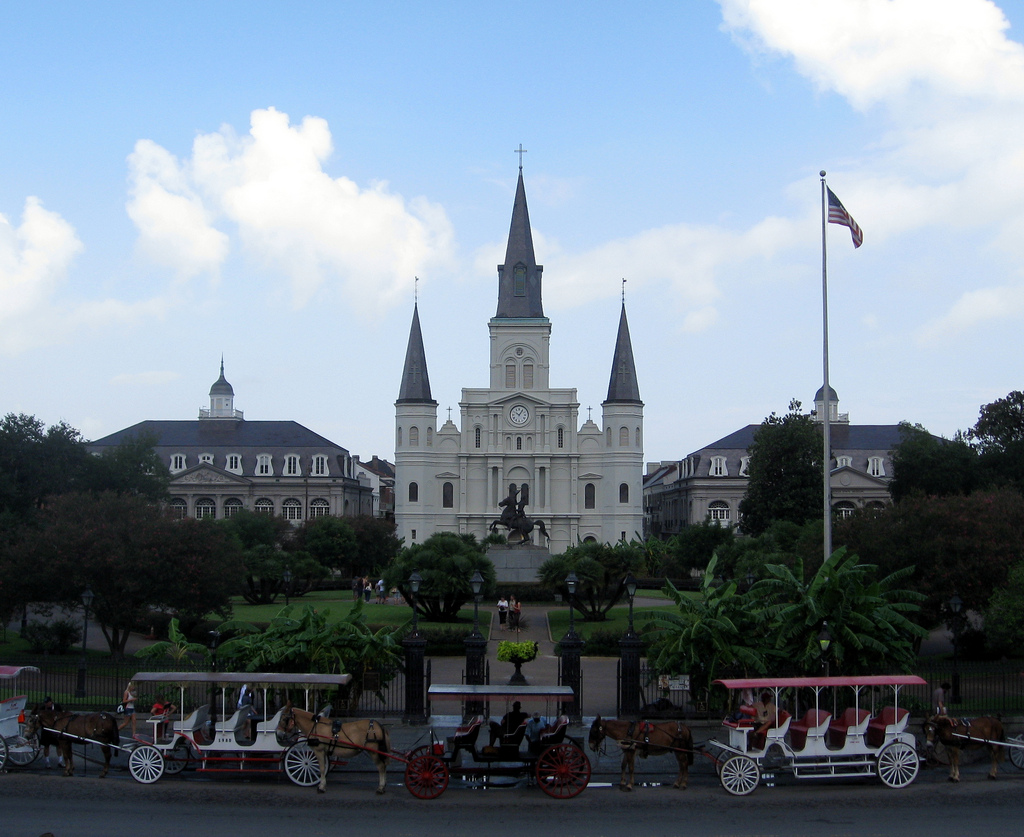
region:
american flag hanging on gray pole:
[816, 176, 862, 257]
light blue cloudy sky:
[3, 6, 1016, 456]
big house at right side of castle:
[639, 410, 949, 543]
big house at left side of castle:
[73, 376, 367, 533]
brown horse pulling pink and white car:
[590, 677, 701, 788]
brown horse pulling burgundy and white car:
[271, 710, 389, 788]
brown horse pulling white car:
[13, 691, 125, 772]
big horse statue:
[490, 480, 552, 545]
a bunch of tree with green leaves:
[10, 417, 1019, 643]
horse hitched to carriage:
[272, 677, 600, 801]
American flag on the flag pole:
[808, 157, 865, 559]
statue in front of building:
[480, 465, 545, 537]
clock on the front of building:
[499, 396, 542, 429]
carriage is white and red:
[708, 669, 923, 793]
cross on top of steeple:
[509, 132, 538, 168]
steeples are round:
[377, 160, 646, 408]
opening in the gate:
[421, 653, 468, 713]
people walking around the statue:
[357, 565, 401, 601]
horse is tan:
[272, 705, 393, 800]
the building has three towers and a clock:
[382, 139, 657, 577]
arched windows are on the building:
[397, 417, 648, 548]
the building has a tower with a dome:
[73, 350, 361, 537]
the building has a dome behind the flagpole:
[670, 373, 975, 579]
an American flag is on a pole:
[803, 167, 870, 580]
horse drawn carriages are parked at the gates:
[22, 670, 947, 816]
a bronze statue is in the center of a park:
[468, 489, 558, 601]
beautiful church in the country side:
[381, 131, 651, 587]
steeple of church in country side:
[394, 267, 437, 410]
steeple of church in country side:
[584, 271, 649, 411]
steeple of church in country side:
[493, 135, 547, 266]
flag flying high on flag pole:
[819, 173, 867, 254]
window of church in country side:
[399, 475, 419, 508]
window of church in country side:
[439, 477, 458, 507]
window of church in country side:
[581, 480, 597, 513]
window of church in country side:
[614, 473, 631, 509]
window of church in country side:
[554, 422, 565, 449]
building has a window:
[555, 425, 568, 457]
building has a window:
[619, 479, 629, 502]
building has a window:
[584, 483, 594, 509]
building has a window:
[444, 480, 452, 506]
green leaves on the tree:
[944, 505, 989, 559]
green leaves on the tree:
[555, 531, 601, 561]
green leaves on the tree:
[441, 568, 480, 597]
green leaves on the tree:
[344, 610, 387, 668]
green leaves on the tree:
[278, 550, 377, 618]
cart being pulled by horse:
[677, 650, 940, 809]